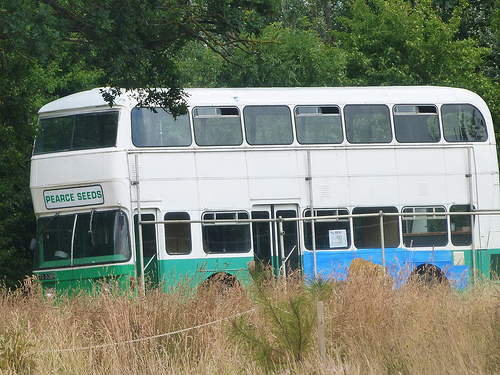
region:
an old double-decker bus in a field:
[24, 86, 496, 319]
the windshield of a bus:
[31, 205, 128, 277]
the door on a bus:
[248, 200, 303, 292]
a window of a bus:
[200, 213, 251, 255]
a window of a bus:
[163, 210, 197, 260]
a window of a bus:
[301, 205, 353, 255]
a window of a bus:
[351, 204, 404, 249]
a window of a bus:
[241, 101, 296, 149]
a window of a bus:
[437, 101, 487, 143]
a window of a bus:
[292, 103, 344, 146]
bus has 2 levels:
[27, 86, 498, 313]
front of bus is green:
[22, 261, 160, 318]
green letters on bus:
[39, 182, 111, 214]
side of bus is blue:
[299, 242, 477, 300]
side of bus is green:
[161, 255, 258, 298]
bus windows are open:
[214, 103, 436, 118]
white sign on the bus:
[329, 227, 356, 249]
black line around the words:
[39, 182, 106, 213]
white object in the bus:
[49, 242, 71, 264]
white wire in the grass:
[1, 282, 303, 369]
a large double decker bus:
[20, 72, 495, 320]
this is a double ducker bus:
[6, 68, 498, 311]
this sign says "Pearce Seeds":
[31, 181, 128, 217]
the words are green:
[31, 177, 131, 212]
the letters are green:
[19, 182, 130, 227]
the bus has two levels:
[15, 65, 497, 330]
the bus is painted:
[12, 78, 497, 322]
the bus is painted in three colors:
[11, 84, 495, 316]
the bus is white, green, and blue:
[28, 75, 495, 330]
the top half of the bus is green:
[12, 82, 496, 204]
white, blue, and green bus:
[24, 82, 498, 307]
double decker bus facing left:
[34, 83, 499, 313]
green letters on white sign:
[41, 182, 108, 211]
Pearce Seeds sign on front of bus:
[43, 182, 105, 209]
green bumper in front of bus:
[35, 253, 140, 307]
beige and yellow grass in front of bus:
[0, 275, 498, 372]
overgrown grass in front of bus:
[0, 255, 498, 372]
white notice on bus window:
[327, 226, 351, 250]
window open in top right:
[193, 103, 245, 146]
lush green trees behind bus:
[0, 0, 499, 291]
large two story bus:
[38, 78, 475, 319]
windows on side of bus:
[130, 100, 442, 152]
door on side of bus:
[252, 198, 308, 315]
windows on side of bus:
[314, 200, 472, 244]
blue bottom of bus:
[312, 250, 476, 294]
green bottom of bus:
[158, 248, 255, 314]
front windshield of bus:
[29, 204, 131, 275]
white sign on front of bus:
[34, 184, 104, 214]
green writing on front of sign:
[47, 189, 112, 206]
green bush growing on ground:
[207, 283, 327, 357]